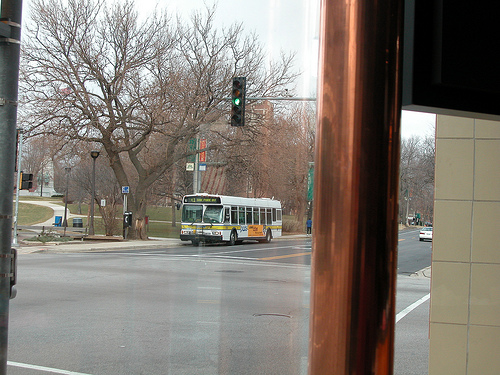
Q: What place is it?
A: It is a pavement.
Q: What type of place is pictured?
A: It is a pavement.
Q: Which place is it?
A: It is a pavement.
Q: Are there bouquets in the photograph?
A: No, there are no bouquets.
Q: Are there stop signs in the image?
A: Yes, there is a stop sign.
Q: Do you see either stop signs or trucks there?
A: Yes, there is a stop sign.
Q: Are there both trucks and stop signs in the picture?
A: No, there is a stop sign but no trucks.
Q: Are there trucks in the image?
A: No, there are no trucks.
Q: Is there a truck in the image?
A: No, there are no trucks.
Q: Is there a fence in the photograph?
A: No, there are no fences.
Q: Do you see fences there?
A: No, there are no fences.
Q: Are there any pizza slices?
A: No, there are no pizza slices.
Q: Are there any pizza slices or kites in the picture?
A: No, there are no pizza slices or kites.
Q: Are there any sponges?
A: No, there are no sponges.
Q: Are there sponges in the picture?
A: No, there are no sponges.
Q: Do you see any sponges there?
A: No, there are no sponges.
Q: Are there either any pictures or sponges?
A: No, there are no sponges or pictures.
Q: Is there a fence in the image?
A: No, there are no fences.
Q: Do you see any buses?
A: Yes, there is a bus.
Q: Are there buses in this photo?
A: Yes, there is a bus.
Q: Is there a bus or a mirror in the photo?
A: Yes, there is a bus.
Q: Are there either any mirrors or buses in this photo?
A: Yes, there is a bus.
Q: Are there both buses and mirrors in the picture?
A: No, there is a bus but no mirrors.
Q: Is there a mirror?
A: No, there are no mirrors.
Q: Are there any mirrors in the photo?
A: No, there are no mirrors.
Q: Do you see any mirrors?
A: No, there are no mirrors.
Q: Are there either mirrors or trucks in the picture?
A: No, there are no mirrors or trucks.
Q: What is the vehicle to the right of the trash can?
A: The vehicle is a bus.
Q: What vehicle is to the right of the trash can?
A: The vehicle is a bus.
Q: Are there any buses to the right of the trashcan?
A: Yes, there is a bus to the right of the trashcan.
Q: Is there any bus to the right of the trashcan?
A: Yes, there is a bus to the right of the trashcan.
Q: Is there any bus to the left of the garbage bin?
A: No, the bus is to the right of the garbage bin.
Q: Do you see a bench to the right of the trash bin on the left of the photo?
A: No, there is a bus to the right of the garbage can.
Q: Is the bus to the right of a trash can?
A: Yes, the bus is to the right of a trash can.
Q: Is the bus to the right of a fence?
A: No, the bus is to the right of a trash can.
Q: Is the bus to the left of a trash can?
A: No, the bus is to the right of a trash can.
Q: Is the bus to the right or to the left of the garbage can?
A: The bus is to the right of the garbage can.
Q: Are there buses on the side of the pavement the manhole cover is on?
A: Yes, there is a bus on the side of the pavement.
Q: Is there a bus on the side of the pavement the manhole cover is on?
A: Yes, there is a bus on the side of the pavement.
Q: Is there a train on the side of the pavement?
A: No, there is a bus on the side of the pavement.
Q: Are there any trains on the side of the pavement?
A: No, there is a bus on the side of the pavement.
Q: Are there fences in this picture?
A: No, there are no fences.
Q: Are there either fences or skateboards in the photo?
A: No, there are no fences or skateboards.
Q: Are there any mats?
A: No, there are no mats.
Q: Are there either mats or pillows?
A: No, there are no mats or pillows.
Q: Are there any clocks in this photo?
A: No, there are no clocks.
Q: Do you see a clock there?
A: No, there are no clocks.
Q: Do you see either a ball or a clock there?
A: No, there are no clocks or balls.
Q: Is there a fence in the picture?
A: No, there are no fences.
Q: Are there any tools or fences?
A: No, there are no fences or tools.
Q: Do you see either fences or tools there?
A: No, there are no fences or tools.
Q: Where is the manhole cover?
A: The manhole cover is on the pavement.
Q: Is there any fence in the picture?
A: No, there are no fences.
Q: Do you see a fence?
A: No, there are no fences.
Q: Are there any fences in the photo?
A: No, there are no fences.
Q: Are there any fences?
A: No, there are no fences.